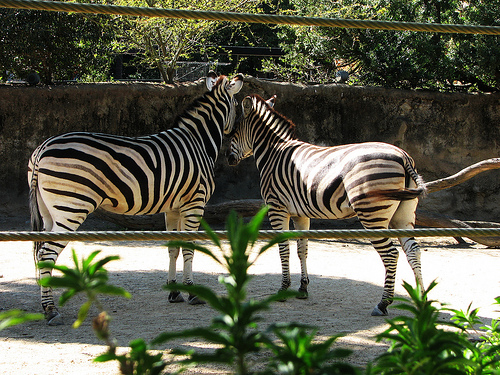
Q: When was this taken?
A: Daytime.